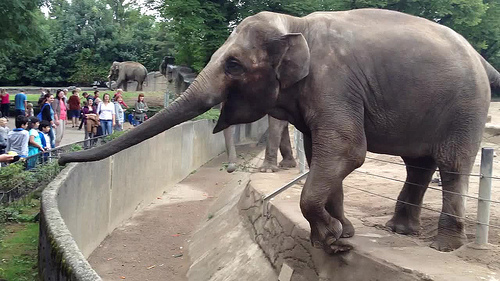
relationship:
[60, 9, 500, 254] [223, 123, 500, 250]
elephant climbing fence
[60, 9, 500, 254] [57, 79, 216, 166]
elephant has trunk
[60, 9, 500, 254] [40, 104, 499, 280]
elephant in pen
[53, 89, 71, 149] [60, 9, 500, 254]
lady watching elephant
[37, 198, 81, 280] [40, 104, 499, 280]
weed on pen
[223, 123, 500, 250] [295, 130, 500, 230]
fence has wire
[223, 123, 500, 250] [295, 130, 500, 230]
fence has some wire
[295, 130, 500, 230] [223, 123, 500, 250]
wire on fence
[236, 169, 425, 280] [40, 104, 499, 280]
stone in pen